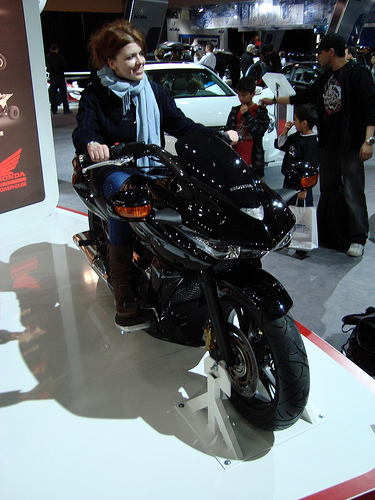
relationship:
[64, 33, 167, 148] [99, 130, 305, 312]
woman on motorcycle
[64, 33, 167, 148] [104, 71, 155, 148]
woman wearing blue scarf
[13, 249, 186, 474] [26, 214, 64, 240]
shadow on ground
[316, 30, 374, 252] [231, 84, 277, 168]
man touching boy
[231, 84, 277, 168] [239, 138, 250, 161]
boy in red shirt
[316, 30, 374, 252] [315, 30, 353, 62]
man in black cap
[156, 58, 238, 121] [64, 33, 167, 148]
white car behind woman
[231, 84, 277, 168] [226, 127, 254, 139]
boy carrying bag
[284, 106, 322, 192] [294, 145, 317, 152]
boy in black shirt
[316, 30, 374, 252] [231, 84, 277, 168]
man next to boy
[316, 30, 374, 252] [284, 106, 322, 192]
man next to boy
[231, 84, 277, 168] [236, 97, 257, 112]
boy touching chin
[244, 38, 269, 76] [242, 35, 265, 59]
guy with white hair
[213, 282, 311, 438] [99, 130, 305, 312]
front wheel of motorcycle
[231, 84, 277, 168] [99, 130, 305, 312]
boy looking at motorcycle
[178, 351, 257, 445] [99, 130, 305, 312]
display stand for motorcycle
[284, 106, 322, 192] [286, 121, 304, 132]
boy picking nose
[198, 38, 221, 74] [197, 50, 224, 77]
bloke wearing white shirt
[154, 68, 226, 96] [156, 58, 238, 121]
windshield of white car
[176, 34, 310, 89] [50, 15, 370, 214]
people at car & bike show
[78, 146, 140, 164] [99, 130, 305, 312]
brake control of motorcycle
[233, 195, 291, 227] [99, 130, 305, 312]
light on motorcycle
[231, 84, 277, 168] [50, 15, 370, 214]
boy at car & bike show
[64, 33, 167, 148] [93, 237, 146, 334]
woman wearing boots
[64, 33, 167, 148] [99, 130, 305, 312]
woman atop motorcycle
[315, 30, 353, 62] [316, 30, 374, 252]
black cap atop man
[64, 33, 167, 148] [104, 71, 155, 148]
woman with blue scarf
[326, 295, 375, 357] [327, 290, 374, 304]
backpack atop floor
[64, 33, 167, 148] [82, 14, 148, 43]
woman has red hair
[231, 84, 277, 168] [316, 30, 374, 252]
boy b man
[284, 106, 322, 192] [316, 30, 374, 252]
boy close to man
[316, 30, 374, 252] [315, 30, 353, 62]
man with black cap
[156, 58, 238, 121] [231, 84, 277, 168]
white car rear of boy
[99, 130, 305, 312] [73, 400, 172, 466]
motorcycle atop platform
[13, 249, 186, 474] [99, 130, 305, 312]
shadow of motorcycle